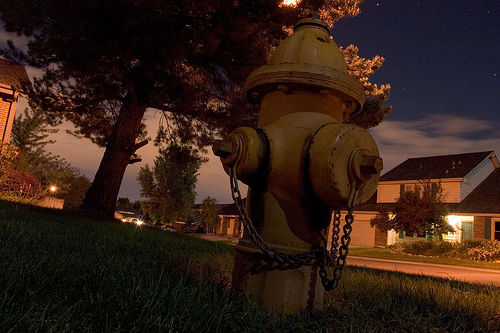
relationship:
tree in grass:
[77, 40, 180, 245] [43, 216, 183, 311]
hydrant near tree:
[227, 38, 362, 321] [77, 40, 180, 245]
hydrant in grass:
[227, 38, 362, 321] [43, 216, 183, 311]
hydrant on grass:
[227, 38, 362, 321] [43, 216, 183, 311]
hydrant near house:
[227, 38, 362, 321] [391, 148, 499, 256]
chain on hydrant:
[284, 168, 376, 292] [227, 38, 362, 321]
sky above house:
[391, 15, 489, 104] [391, 148, 499, 256]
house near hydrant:
[391, 148, 499, 256] [227, 38, 362, 321]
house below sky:
[391, 148, 499, 256] [391, 15, 489, 104]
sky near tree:
[391, 15, 489, 104] [77, 40, 180, 245]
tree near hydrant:
[77, 40, 180, 245] [227, 38, 362, 321]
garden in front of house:
[354, 232, 493, 269] [347, 158, 497, 257]